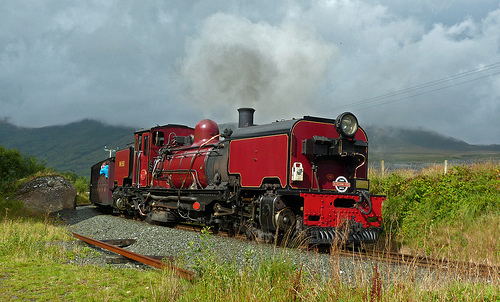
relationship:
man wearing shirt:
[99, 159, 111, 179] [100, 166, 107, 178]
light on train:
[328, 107, 366, 145] [86, 105, 388, 257]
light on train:
[337, 111, 360, 133] [86, 105, 388, 257]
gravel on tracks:
[69, 234, 399, 276] [158, 212, 498, 278]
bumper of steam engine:
[304, 211, 399, 258] [52, 61, 433, 259]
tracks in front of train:
[158, 212, 498, 278] [86, 105, 388, 257]